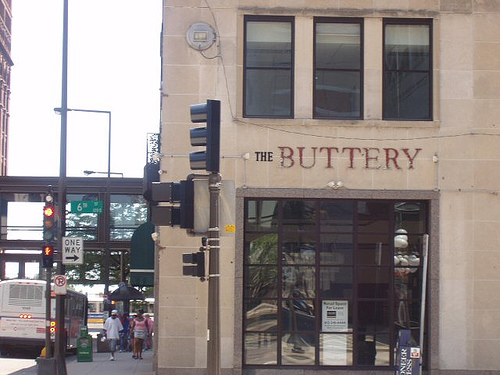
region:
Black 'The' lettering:
[254, 143, 280, 172]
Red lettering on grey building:
[278, 131, 430, 179]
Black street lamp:
[37, 201, 61, 278]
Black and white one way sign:
[60, 234, 85, 271]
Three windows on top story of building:
[235, 1, 445, 135]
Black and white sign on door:
[312, 291, 367, 334]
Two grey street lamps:
[44, 92, 154, 221]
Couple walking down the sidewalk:
[92, 296, 169, 367]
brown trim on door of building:
[244, 197, 447, 374]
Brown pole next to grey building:
[194, 178, 246, 373]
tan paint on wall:
[166, 345, 187, 361]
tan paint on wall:
[173, 308, 192, 314]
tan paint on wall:
[166, 280, 183, 295]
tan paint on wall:
[448, 321, 478, 325]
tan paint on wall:
[453, 247, 473, 259]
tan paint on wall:
[451, 203, 468, 214]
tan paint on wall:
[461, 170, 465, 174]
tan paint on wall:
[446, 95, 467, 120]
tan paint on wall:
[452, 43, 469, 81]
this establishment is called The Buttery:
[248, 140, 424, 174]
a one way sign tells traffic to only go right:
[58, 234, 86, 266]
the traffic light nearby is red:
[38, 200, 55, 245]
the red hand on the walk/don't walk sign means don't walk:
[38, 243, 55, 270]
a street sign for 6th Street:
[68, 196, 106, 216]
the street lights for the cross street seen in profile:
[147, 95, 227, 280]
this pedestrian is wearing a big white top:
[101, 308, 128, 360]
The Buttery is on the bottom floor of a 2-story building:
[156, 0, 498, 373]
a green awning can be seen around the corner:
[126, 219, 156, 288]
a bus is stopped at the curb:
[0, 272, 92, 354]